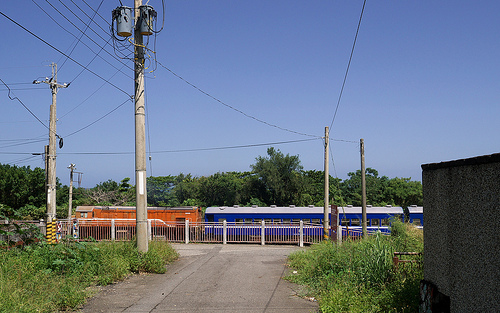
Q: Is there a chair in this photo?
A: No, there are no chairs.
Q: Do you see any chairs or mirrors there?
A: No, there are no chairs or mirrors.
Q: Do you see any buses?
A: No, there are no buses.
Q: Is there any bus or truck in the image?
A: No, there are no buses or trucks.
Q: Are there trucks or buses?
A: No, there are no buses or trucks.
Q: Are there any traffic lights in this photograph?
A: No, there are no traffic lights.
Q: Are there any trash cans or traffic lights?
A: No, there are no traffic lights or trash cans.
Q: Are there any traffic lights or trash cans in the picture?
A: No, there are no traffic lights or trash cans.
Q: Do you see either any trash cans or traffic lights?
A: No, there are no traffic lights or trash cans.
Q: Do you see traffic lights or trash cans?
A: No, there are no traffic lights or trash cans.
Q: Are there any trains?
A: Yes, there is a train.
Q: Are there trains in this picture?
A: Yes, there is a train.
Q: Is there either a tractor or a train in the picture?
A: Yes, there is a train.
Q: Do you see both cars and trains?
A: Yes, there are both a train and cars.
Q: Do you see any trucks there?
A: No, there are no trucks.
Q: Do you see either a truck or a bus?
A: No, there are no trucks or buses.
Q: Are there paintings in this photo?
A: No, there are no paintings.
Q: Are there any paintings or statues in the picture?
A: No, there are no paintings or statues.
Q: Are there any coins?
A: No, there are no coins.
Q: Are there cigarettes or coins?
A: No, there are no coins or cigarettes.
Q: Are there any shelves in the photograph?
A: No, there are no shelves.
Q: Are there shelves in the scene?
A: No, there are no shelves.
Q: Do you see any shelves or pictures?
A: No, there are no shelves or pictures.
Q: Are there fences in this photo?
A: Yes, there is a fence.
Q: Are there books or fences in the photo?
A: Yes, there is a fence.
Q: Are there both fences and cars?
A: Yes, there are both a fence and a car.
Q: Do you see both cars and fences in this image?
A: Yes, there are both a fence and a car.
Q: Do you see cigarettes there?
A: No, there are no cigarettes.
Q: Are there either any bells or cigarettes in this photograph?
A: No, there are no cigarettes or bells.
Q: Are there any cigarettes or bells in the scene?
A: No, there are no cigarettes or bells.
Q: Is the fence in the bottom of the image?
A: Yes, the fence is in the bottom of the image.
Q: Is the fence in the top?
A: No, the fence is in the bottom of the image.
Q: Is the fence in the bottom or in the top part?
A: The fence is in the bottom of the image.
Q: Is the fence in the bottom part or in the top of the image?
A: The fence is in the bottom of the image.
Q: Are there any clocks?
A: Yes, there is a clock.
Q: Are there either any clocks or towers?
A: Yes, there is a clock.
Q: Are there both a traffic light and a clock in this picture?
A: No, there is a clock but no traffic lights.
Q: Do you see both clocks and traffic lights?
A: No, there is a clock but no traffic lights.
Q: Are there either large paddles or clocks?
A: Yes, there is a large clock.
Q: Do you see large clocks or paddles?
A: Yes, there is a large clock.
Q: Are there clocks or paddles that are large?
A: Yes, the clock is large.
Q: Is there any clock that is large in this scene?
A: Yes, there is a large clock.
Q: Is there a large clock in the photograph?
A: Yes, there is a large clock.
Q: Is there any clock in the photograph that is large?
A: Yes, there is a clock that is large.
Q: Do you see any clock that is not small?
A: Yes, there is a large clock.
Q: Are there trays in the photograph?
A: No, there are no trays.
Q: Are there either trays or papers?
A: No, there are no trays or papers.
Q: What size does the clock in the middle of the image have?
A: The clock has large size.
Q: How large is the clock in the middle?
A: The clock is large.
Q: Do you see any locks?
A: No, there are no locks.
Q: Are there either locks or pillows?
A: No, there are no locks or pillows.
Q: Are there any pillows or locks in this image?
A: No, there are no locks or pillows.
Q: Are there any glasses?
A: No, there are no glasses.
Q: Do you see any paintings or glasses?
A: No, there are no glasses or paintings.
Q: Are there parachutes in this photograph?
A: No, there are no parachutes.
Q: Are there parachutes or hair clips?
A: No, there are no parachutes or hair clips.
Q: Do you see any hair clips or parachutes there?
A: No, there are no parachutes or hair clips.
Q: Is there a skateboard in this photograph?
A: No, there are no skateboards.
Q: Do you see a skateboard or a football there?
A: No, there are no skateboards or footballs.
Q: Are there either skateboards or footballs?
A: No, there are no skateboards or footballs.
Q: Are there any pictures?
A: No, there are no pictures.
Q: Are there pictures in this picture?
A: No, there are no pictures.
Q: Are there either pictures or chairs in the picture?
A: No, there are no pictures or chairs.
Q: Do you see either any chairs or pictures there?
A: No, there are no pictures or chairs.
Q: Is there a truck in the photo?
A: No, there are no trucks.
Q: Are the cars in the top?
A: No, the cars are in the bottom of the image.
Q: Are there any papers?
A: No, there are no papers.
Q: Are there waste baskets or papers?
A: No, there are no papers or waste baskets.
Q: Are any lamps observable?
A: No, there are no lamps.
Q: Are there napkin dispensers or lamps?
A: No, there are no lamps or napkin dispensers.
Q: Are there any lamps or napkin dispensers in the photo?
A: No, there are no lamps or napkin dispensers.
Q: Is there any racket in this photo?
A: No, there are no rackets.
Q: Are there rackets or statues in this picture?
A: No, there are no rackets or statues.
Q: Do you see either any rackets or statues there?
A: No, there are no rackets or statues.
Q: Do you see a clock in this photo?
A: Yes, there is a clock.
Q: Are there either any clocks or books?
A: Yes, there is a clock.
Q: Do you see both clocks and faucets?
A: No, there is a clock but no faucets.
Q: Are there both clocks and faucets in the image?
A: No, there is a clock but no faucets.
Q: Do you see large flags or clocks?
A: Yes, there is a large clock.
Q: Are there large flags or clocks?
A: Yes, there is a large clock.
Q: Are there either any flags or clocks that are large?
A: Yes, the clock is large.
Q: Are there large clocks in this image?
A: Yes, there is a large clock.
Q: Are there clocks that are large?
A: Yes, there is a clock that is large.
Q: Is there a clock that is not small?
A: Yes, there is a large clock.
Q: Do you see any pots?
A: No, there are no pots.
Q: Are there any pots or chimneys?
A: No, there are no pots or chimneys.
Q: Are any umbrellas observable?
A: No, there are no umbrellas.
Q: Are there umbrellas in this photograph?
A: No, there are no umbrellas.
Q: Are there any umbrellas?
A: No, there are no umbrellas.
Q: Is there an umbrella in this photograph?
A: No, there are no umbrellas.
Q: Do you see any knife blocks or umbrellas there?
A: No, there are no umbrellas or knife blocks.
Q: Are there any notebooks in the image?
A: No, there are no notebooks.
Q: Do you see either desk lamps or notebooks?
A: No, there are no notebooks or desk lamps.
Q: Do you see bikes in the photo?
A: No, there are no bikes.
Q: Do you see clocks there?
A: Yes, there is a clock.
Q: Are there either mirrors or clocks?
A: Yes, there is a clock.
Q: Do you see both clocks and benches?
A: No, there is a clock but no benches.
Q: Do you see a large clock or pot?
A: Yes, there is a large clock.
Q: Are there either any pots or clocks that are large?
A: Yes, the clock is large.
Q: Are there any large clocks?
A: Yes, there is a large clock.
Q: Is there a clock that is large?
A: Yes, there is a clock that is large.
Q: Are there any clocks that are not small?
A: Yes, there is a large clock.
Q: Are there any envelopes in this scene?
A: No, there are no envelopes.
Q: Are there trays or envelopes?
A: No, there are no envelopes or trays.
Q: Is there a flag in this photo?
A: No, there are no flags.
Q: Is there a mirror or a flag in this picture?
A: No, there are no flags or mirrors.